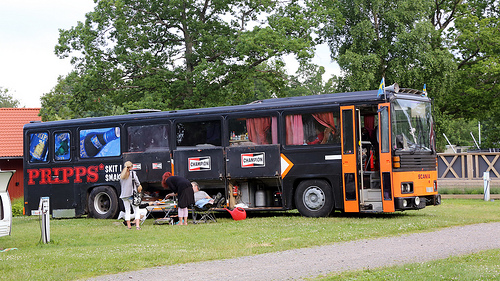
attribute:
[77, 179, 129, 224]
tire — big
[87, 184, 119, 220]
wheel — rear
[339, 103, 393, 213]
doors — orange, open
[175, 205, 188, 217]
pants — white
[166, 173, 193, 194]
shirt — black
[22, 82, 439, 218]
bus — dark colored, orange, black, tan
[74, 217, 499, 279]
pathway — gray, gravel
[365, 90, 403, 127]
corner — top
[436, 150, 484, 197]
fencing — black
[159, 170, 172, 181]
hair — red